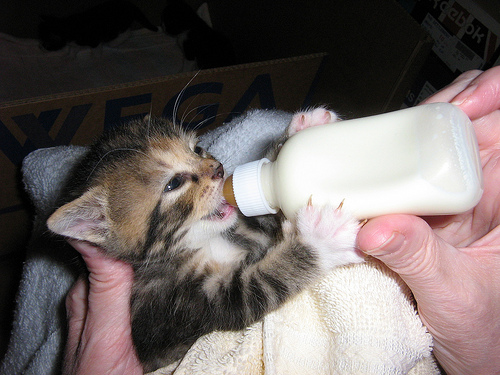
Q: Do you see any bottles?
A: Yes, there is a bottle.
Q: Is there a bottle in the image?
A: Yes, there is a bottle.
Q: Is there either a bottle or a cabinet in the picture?
A: Yes, there is a bottle.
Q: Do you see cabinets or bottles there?
A: Yes, there is a bottle.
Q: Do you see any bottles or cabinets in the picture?
A: Yes, there is a bottle.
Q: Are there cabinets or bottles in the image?
A: Yes, there is a bottle.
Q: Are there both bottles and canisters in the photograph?
A: No, there is a bottle but no canisters.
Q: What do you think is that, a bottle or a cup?
A: That is a bottle.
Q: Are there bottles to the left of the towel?
A: No, the bottle is to the right of the towel.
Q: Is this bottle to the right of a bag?
A: No, the bottle is to the right of the towel.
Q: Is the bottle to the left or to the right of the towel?
A: The bottle is to the right of the towel.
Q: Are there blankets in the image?
A: Yes, there is a blanket.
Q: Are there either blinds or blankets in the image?
A: Yes, there is a blanket.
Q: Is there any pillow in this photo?
A: No, there are no pillows.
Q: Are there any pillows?
A: No, there are no pillows.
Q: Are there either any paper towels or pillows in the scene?
A: No, there are no pillows or paper towels.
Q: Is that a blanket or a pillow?
A: That is a blanket.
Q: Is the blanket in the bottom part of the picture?
A: Yes, the blanket is in the bottom of the image.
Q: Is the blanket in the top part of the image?
A: No, the blanket is in the bottom of the image.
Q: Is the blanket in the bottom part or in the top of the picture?
A: The blanket is in the bottom of the image.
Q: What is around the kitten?
A: The blanket is around the kitten.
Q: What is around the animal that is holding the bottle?
A: The blanket is around the kitten.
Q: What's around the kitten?
A: The blanket is around the kitten.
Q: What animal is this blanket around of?
A: The blanket is around the kitten.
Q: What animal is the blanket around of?
A: The blanket is around the kitten.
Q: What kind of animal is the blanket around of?
A: The blanket is around the kitten.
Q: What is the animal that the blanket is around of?
A: The animal is a kitten.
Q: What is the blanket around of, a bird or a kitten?
A: The blanket is around a kitten.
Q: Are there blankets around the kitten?
A: Yes, there is a blanket around the kitten.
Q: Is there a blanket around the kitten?
A: Yes, there is a blanket around the kitten.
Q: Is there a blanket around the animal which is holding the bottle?
A: Yes, there is a blanket around the kitten.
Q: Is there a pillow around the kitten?
A: No, there is a blanket around the kitten.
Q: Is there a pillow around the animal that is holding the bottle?
A: No, there is a blanket around the kitten.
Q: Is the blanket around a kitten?
A: Yes, the blanket is around a kitten.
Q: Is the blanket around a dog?
A: No, the blanket is around a kitten.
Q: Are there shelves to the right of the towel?
A: No, there is a blanket to the right of the towel.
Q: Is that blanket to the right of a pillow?
A: No, the blanket is to the right of the towel.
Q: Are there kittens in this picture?
A: Yes, there is a kitten.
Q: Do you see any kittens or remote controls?
A: Yes, there is a kitten.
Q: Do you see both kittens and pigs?
A: No, there is a kitten but no pigs.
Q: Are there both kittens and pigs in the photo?
A: No, there is a kitten but no pigs.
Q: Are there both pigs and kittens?
A: No, there is a kitten but no pigs.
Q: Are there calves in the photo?
A: No, there are no calves.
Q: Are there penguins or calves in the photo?
A: No, there are no calves or penguins.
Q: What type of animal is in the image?
A: The animal is a kitten.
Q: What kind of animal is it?
A: The animal is a kitten.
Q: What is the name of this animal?
A: This is a kitten.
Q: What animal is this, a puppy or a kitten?
A: This is a kitten.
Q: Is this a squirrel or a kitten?
A: This is a kitten.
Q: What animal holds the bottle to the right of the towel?
A: The animal is a kitten.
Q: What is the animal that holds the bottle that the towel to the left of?
A: The animal is a kitten.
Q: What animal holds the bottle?
A: The animal is a kitten.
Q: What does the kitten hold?
A: The kitten holds the bottle.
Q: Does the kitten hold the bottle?
A: Yes, the kitten holds the bottle.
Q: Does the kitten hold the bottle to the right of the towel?
A: Yes, the kitten holds the bottle.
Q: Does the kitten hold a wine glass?
A: No, the kitten holds the bottle.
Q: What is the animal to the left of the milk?
A: The animal is a kitten.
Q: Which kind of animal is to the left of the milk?
A: The animal is a kitten.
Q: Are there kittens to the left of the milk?
A: Yes, there is a kitten to the left of the milk.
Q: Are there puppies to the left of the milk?
A: No, there is a kitten to the left of the milk.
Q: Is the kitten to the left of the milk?
A: Yes, the kitten is to the left of the milk.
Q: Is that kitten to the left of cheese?
A: No, the kitten is to the left of the milk.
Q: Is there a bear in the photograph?
A: No, there are no bears.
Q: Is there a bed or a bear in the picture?
A: No, there are no bears or beds.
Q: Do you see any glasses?
A: No, there are no glasses.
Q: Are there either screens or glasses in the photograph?
A: No, there are no glasses or screens.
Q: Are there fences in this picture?
A: No, there are no fences.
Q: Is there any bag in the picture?
A: No, there are no bags.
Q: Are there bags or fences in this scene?
A: No, there are no bags or fences.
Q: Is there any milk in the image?
A: Yes, there is milk.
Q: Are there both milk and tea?
A: No, there is milk but no tea.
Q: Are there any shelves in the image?
A: No, there are no shelves.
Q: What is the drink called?
A: The drink is milk.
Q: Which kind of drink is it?
A: The drink is milk.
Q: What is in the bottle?
A: The milk is in the bottle.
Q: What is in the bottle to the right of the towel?
A: The milk is in the bottle.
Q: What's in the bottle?
A: The milk is in the bottle.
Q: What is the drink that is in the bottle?
A: The drink is milk.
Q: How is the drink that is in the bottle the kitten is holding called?
A: The drink is milk.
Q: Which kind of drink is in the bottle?
A: The drink is milk.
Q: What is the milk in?
A: The milk is in the bottle.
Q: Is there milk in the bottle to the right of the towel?
A: Yes, there is milk in the bottle.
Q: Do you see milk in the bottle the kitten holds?
A: Yes, there is milk in the bottle.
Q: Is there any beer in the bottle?
A: No, there is milk in the bottle.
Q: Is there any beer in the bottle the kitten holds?
A: No, there is milk in the bottle.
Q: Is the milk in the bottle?
A: Yes, the milk is in the bottle.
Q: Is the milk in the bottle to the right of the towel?
A: Yes, the milk is in the bottle.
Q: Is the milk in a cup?
A: No, the milk is in the bottle.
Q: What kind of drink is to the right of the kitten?
A: The drink is milk.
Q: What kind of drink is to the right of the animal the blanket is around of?
A: The drink is milk.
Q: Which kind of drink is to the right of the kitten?
A: The drink is milk.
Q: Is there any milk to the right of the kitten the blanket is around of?
A: Yes, there is milk to the right of the kitten.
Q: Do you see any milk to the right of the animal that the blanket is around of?
A: Yes, there is milk to the right of the kitten.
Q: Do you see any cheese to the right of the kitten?
A: No, there is milk to the right of the kitten.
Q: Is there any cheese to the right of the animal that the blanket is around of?
A: No, there is milk to the right of the kitten.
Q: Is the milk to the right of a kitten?
A: Yes, the milk is to the right of a kitten.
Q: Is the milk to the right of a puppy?
A: No, the milk is to the right of a kitten.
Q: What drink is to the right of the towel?
A: The drink is milk.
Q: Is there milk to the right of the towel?
A: Yes, there is milk to the right of the towel.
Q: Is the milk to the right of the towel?
A: Yes, the milk is to the right of the towel.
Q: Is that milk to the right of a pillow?
A: No, the milk is to the right of the towel.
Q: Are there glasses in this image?
A: No, there are no glasses.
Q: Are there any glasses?
A: No, there are no glasses.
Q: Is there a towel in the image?
A: Yes, there is a towel.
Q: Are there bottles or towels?
A: Yes, there is a towel.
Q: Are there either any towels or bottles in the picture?
A: Yes, there is a towel.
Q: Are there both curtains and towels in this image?
A: No, there is a towel but no curtains.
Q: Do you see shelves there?
A: No, there are no shelves.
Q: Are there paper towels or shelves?
A: No, there are no shelves or paper towels.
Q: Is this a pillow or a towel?
A: This is a towel.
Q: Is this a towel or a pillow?
A: This is a towel.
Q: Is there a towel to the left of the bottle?
A: Yes, there is a towel to the left of the bottle.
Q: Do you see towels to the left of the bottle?
A: Yes, there is a towel to the left of the bottle.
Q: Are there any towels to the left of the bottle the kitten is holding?
A: Yes, there is a towel to the left of the bottle.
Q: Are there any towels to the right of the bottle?
A: No, the towel is to the left of the bottle.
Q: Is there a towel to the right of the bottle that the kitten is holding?
A: No, the towel is to the left of the bottle.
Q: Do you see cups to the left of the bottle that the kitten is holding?
A: No, there is a towel to the left of the bottle.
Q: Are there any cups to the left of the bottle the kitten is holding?
A: No, there is a towel to the left of the bottle.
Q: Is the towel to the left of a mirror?
A: No, the towel is to the left of the bottle.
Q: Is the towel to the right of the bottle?
A: No, the towel is to the left of the bottle.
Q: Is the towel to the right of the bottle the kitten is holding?
A: No, the towel is to the left of the bottle.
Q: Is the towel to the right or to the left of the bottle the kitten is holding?
A: The towel is to the left of the bottle.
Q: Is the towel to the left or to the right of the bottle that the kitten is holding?
A: The towel is to the left of the bottle.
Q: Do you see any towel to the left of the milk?
A: Yes, there is a towel to the left of the milk.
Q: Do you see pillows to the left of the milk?
A: No, there is a towel to the left of the milk.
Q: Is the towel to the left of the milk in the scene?
A: Yes, the towel is to the left of the milk.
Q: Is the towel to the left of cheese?
A: No, the towel is to the left of the milk.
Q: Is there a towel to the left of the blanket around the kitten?
A: Yes, there is a towel to the left of the blanket.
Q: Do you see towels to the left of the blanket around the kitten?
A: Yes, there is a towel to the left of the blanket.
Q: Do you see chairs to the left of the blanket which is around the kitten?
A: No, there is a towel to the left of the blanket.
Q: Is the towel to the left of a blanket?
A: Yes, the towel is to the left of a blanket.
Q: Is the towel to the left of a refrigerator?
A: No, the towel is to the left of a blanket.